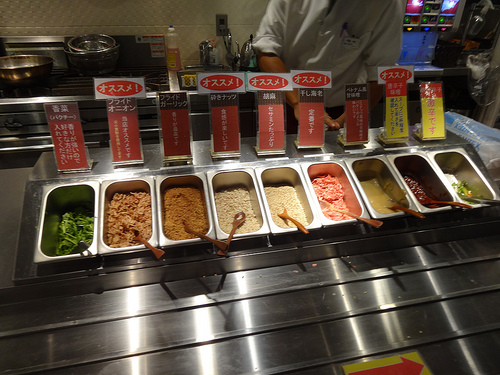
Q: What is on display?
A: Condiments.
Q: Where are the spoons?
A: Container.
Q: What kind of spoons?
A: Wooden.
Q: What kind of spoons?
A: Wooden.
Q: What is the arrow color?
A: Red.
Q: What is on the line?
A: Containers.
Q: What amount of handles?
A: Nine.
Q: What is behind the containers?
A: Labels.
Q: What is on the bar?
A: Various food buffet style.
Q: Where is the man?
A: Behind the food.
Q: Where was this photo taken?
A: A restaurant.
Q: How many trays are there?
A: Nine.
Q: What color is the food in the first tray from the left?
A: Green.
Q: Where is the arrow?
A: Bottom right.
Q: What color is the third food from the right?
A: Yellow.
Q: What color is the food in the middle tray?
A: White.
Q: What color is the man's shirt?
A: Grey.